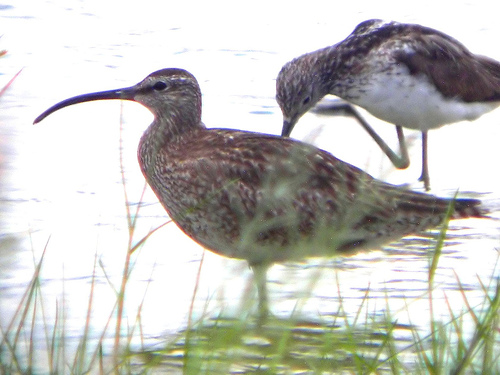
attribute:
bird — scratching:
[257, 32, 489, 191]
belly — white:
[337, 69, 464, 147]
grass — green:
[46, 186, 447, 362]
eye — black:
[152, 66, 188, 109]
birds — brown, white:
[43, 55, 448, 308]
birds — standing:
[23, 24, 475, 289]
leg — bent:
[300, 90, 444, 190]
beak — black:
[40, 87, 146, 141]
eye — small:
[141, 80, 178, 109]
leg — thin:
[241, 232, 319, 345]